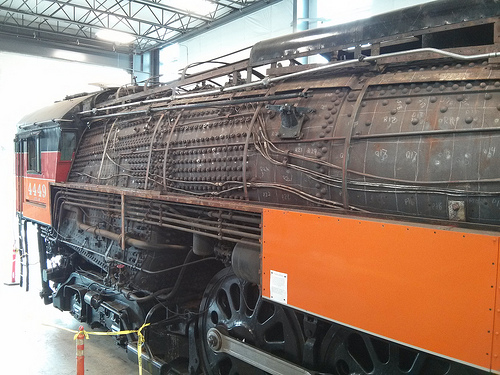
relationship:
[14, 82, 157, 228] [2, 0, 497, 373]
front of train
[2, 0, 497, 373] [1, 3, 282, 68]
train under roof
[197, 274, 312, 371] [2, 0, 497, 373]
wheel of train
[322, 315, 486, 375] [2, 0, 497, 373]
wheel of train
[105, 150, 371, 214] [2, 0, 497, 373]
wire of train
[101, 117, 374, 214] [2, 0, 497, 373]
wire of train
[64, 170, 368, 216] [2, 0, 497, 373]
wire of train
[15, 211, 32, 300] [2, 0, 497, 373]
stair to train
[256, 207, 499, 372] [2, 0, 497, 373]
panel on train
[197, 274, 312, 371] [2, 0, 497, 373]
wheel for train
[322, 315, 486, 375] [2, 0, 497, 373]
wheel for train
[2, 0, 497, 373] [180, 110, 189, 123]
train has rivet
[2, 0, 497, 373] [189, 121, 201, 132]
train has rivet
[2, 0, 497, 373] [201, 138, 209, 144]
train has rivet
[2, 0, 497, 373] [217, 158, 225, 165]
train has rivet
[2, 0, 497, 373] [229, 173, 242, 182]
train has rivet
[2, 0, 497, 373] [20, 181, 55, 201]
train has number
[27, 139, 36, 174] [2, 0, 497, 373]
window on train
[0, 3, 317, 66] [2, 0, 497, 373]
scaffolding above train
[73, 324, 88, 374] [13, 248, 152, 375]
post with tape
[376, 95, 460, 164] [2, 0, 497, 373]
chalk writing on train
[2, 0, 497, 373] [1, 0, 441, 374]
train inside building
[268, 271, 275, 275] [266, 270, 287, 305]
screw on white sign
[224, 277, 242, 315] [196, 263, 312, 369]
groove on wheel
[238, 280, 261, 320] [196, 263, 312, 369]
groove on wheel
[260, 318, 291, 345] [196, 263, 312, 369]
groove on wheel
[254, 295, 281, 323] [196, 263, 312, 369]
groove on wheel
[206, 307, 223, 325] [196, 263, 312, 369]
groove on wheel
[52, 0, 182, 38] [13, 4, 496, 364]
beam suspended above train depot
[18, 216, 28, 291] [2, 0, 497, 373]
ladder on train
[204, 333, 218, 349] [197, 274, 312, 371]
screw on wheel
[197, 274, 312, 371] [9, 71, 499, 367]
wheel on train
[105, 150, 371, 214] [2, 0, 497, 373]
wire running across train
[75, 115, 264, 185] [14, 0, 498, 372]
steel rivets on locomotive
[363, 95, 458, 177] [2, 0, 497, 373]
chalk writing on train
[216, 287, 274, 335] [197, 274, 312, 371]
spokes of wheel